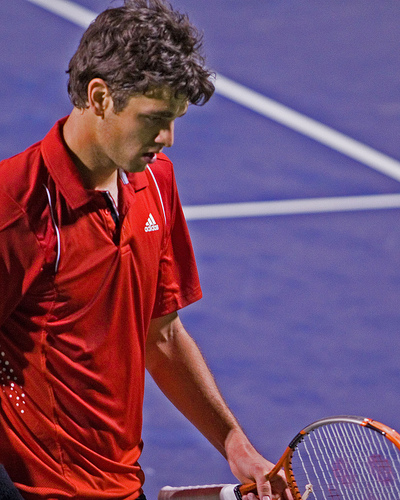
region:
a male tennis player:
[1, 2, 294, 499]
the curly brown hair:
[65, 7, 212, 113]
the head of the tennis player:
[60, 4, 200, 173]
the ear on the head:
[86, 78, 112, 116]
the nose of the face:
[152, 120, 177, 146]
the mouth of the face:
[140, 146, 158, 162]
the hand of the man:
[224, 429, 287, 499]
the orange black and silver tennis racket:
[156, 415, 398, 499]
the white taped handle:
[159, 478, 240, 499]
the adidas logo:
[144, 212, 161, 232]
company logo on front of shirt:
[140, 209, 164, 238]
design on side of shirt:
[0, 344, 40, 416]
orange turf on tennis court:
[231, 246, 360, 344]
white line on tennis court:
[204, 180, 357, 225]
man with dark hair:
[35, 8, 217, 173]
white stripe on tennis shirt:
[36, 179, 66, 276]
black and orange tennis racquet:
[137, 390, 398, 498]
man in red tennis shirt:
[4, 10, 263, 498]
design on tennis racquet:
[322, 446, 392, 487]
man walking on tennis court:
[0, 0, 317, 493]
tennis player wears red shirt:
[4, 1, 290, 498]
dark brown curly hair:
[58, 3, 219, 123]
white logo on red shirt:
[139, 207, 159, 236]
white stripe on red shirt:
[42, 178, 65, 280]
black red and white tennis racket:
[151, 413, 399, 497]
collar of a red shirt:
[34, 117, 151, 216]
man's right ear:
[84, 75, 113, 117]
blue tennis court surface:
[4, 2, 399, 498]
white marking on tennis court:
[46, 1, 398, 180]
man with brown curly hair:
[72, 0, 216, 168]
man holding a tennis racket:
[161, 412, 393, 492]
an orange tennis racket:
[164, 416, 392, 496]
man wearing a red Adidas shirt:
[4, 153, 196, 485]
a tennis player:
[4, 4, 372, 496]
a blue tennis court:
[218, 13, 399, 262]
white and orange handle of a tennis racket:
[151, 480, 235, 496]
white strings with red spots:
[316, 429, 390, 498]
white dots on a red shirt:
[2, 339, 35, 416]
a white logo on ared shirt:
[131, 206, 167, 236]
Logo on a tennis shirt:
[141, 209, 165, 233]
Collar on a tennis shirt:
[34, 112, 94, 212]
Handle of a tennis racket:
[157, 481, 241, 499]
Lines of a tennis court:
[250, 181, 348, 221]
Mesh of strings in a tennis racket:
[304, 444, 387, 494]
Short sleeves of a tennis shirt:
[133, 226, 204, 324]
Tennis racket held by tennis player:
[150, 417, 398, 498]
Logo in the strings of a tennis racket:
[321, 446, 394, 496]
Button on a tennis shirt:
[95, 201, 117, 219]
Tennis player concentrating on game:
[37, 7, 231, 179]